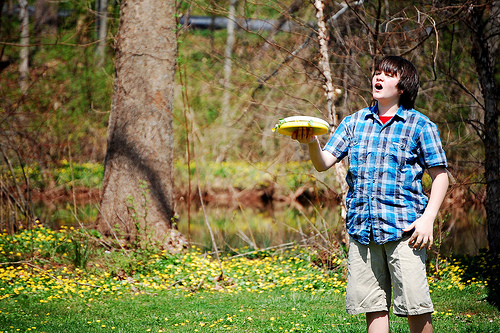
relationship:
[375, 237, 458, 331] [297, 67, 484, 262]
leg of a boy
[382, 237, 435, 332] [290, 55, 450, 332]
leg of boy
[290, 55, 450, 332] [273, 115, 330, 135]
boy holds frisbees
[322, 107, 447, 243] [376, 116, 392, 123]
blue shirt under t-shirt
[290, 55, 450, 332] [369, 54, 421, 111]
boy has black hair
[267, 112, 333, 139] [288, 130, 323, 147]
frisbees in hand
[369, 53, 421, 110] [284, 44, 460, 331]
black hair on boy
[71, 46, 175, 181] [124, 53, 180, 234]
tree has trunk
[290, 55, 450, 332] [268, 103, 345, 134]
boy has frsibee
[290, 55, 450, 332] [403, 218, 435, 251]
boy has hand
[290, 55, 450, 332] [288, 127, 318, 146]
boy has hand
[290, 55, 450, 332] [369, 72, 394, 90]
boy has nose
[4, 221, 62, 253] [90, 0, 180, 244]
flowers are in tree trunk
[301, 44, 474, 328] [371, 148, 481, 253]
boy has arm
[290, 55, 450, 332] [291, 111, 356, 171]
boy has arm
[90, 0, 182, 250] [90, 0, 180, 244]
tree has tree trunk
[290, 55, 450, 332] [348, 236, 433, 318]
boy wears shorts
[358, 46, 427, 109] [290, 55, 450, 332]
head on boy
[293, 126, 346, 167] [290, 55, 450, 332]
arm on boy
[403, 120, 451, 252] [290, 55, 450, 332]
arm on boy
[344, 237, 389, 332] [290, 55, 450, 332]
leg on boy